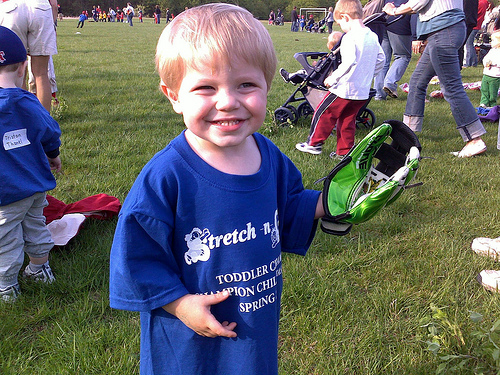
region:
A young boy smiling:
[150, 30, 281, 153]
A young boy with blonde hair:
[153, 32, 277, 155]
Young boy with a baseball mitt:
[146, 77, 431, 236]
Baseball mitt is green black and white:
[318, 115, 425, 234]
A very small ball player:
[0, 46, 62, 301]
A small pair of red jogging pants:
[298, 99, 368, 157]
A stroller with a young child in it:
[280, 37, 340, 124]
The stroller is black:
[277, 56, 332, 125]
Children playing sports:
[76, 0, 159, 28]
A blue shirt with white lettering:
[131, 152, 316, 342]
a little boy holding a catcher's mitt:
[100, 5, 417, 367]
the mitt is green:
[322, 119, 425, 236]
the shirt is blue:
[100, 126, 321, 373]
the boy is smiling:
[162, 44, 267, 153]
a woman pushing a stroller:
[265, 0, 493, 160]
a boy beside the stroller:
[300, 0, 386, 159]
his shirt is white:
[325, 23, 387, 104]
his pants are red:
[306, 89, 366, 155]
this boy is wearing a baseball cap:
[0, 22, 20, 65]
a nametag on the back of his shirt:
[0, 123, 34, 152]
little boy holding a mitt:
[78, 1, 429, 373]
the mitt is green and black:
[282, 103, 458, 255]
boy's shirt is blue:
[97, 110, 326, 362]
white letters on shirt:
[128, 128, 313, 352]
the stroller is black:
[269, 23, 364, 125]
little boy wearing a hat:
[0, 14, 74, 100]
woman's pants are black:
[393, 10, 488, 152]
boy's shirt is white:
[331, 28, 378, 93]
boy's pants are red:
[306, 74, 383, 163]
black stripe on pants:
[306, 71, 339, 151]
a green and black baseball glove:
[318, 117, 431, 242]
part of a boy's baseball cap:
[0, 26, 30, 67]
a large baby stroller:
[275, 9, 405, 131]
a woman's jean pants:
[403, 20, 485, 140]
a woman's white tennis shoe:
[445, 138, 488, 157]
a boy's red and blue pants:
[307, 91, 367, 156]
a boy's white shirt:
[328, 17, 385, 101]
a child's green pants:
[481, 73, 498, 103]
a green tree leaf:
[412, 295, 498, 372]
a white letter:
[231, 229, 240, 243]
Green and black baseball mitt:
[320, 122, 425, 230]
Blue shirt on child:
[104, 123, 324, 373]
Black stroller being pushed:
[272, 39, 336, 126]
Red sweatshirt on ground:
[40, 182, 125, 257]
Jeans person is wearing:
[400, 17, 487, 144]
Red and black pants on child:
[305, 87, 367, 158]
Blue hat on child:
[0, 22, 32, 72]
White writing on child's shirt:
[182, 209, 292, 330]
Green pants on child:
[474, 71, 499, 111]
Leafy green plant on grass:
[410, 295, 499, 373]